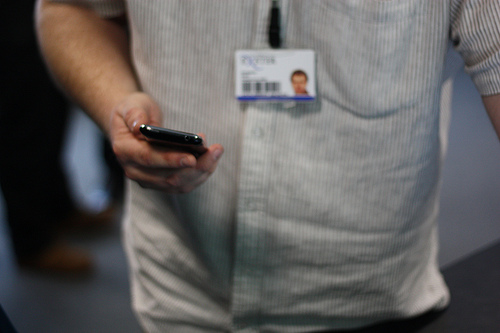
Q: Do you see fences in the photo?
A: No, there are no fences.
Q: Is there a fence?
A: No, there are no fences.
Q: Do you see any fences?
A: No, there are no fences.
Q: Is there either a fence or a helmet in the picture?
A: No, there are no fences or helmets.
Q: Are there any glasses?
A: No, there are no glasses.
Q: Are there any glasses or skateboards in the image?
A: No, there are no glasses or skateboards.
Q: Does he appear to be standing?
A: Yes, the guy is standing.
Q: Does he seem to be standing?
A: Yes, the guy is standing.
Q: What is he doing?
A: The guy is standing.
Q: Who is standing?
A: The guy is standing.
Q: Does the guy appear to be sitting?
A: No, the guy is standing.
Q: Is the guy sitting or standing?
A: The guy is standing.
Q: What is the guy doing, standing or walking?
A: The guy is standing.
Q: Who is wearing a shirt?
A: The guy is wearing a shirt.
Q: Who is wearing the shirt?
A: The guy is wearing a shirt.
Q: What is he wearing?
A: The guy is wearing a shirt.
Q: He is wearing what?
A: The guy is wearing a shirt.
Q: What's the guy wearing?
A: The guy is wearing a shirt.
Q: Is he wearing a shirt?
A: Yes, the guy is wearing a shirt.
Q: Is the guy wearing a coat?
A: No, the guy is wearing a shirt.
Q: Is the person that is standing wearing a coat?
A: No, the guy is wearing a shirt.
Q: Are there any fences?
A: No, there are no fences.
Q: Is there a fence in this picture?
A: No, there are no fences.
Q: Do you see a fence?
A: No, there are no fences.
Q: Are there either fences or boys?
A: No, there are no fences or boys.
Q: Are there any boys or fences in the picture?
A: No, there are no fences or boys.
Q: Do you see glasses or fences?
A: No, there are no glasses or fences.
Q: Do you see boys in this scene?
A: No, there are no boys.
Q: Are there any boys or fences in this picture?
A: No, there are no boys or fences.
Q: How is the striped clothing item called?
A: The clothing item is a shirt.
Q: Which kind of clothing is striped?
A: The clothing is a shirt.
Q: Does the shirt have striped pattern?
A: Yes, the shirt is striped.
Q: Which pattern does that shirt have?
A: The shirt has striped pattern.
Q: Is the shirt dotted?
A: No, the shirt is striped.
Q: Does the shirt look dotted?
A: No, the shirt is striped.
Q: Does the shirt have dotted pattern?
A: No, the shirt is striped.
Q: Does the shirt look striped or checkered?
A: The shirt is striped.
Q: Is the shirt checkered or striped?
A: The shirt is striped.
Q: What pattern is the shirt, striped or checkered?
A: The shirt is striped.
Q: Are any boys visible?
A: No, there are no boys.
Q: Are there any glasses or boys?
A: No, there are no boys or glasses.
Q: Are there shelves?
A: No, there are no shelves.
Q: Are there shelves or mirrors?
A: No, there are no shelves or mirrors.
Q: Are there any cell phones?
A: Yes, there is a cell phone.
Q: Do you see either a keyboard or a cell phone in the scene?
A: Yes, there is a cell phone.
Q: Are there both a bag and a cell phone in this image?
A: No, there is a cell phone but no bags.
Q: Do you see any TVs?
A: No, there are no tvs.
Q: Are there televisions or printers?
A: No, there are no televisions or printers.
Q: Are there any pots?
A: No, there are no pots.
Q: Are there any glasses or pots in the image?
A: No, there are no pots or glasses.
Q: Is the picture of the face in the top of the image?
A: Yes, the picture is in the top of the image.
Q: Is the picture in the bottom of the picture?
A: No, the picture is in the top of the image.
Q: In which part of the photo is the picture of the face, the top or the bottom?
A: The picture is in the top of the image.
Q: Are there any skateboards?
A: No, there are no skateboards.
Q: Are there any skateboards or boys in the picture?
A: No, there are no skateboards or boys.